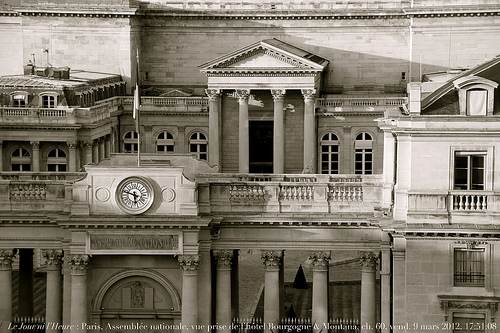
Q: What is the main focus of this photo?
A: A building.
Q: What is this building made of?
A: Bricks.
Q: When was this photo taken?
A: Outside, during the daytime.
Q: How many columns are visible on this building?
A: 12.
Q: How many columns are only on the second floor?
A: Four.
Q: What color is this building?
A: White.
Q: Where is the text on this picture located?
A: At the bottom.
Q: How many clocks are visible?
A: One.